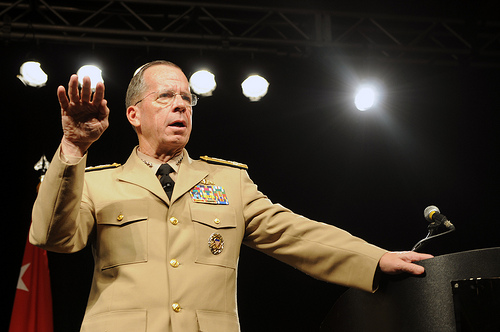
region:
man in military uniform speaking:
[20, 45, 470, 310]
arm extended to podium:
[245, 162, 430, 302]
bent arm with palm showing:
[22, 60, 112, 260]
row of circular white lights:
[5, 52, 295, 118]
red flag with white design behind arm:
[5, 145, 60, 320]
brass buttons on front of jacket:
[105, 196, 230, 316]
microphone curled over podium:
[401, 187, 456, 282]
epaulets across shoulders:
[81, 146, 253, 173]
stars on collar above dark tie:
[120, 150, 226, 206]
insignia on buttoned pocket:
[185, 208, 241, 263]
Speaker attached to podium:
[413, 198, 486, 250]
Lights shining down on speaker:
[198, 60, 401, 125]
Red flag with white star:
[14, 150, 57, 327]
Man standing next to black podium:
[32, 45, 454, 328]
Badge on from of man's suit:
[207, 229, 228, 256]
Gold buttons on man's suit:
[160, 207, 185, 317]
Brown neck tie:
[152, 162, 185, 202]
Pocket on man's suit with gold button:
[99, 195, 157, 275]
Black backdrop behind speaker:
[286, 120, 461, 199]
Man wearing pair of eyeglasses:
[126, 70, 205, 140]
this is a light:
[340, 79, 390, 117]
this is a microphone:
[421, 195, 449, 237]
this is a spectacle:
[154, 89, 198, 103]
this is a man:
[43, 67, 265, 327]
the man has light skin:
[143, 111, 160, 140]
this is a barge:
[196, 183, 222, 203]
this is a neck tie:
[160, 163, 170, 185]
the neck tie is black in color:
[163, 175, 165, 178]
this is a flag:
[21, 258, 53, 330]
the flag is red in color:
[31, 306, 41, 317]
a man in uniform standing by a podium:
[30, 62, 433, 329]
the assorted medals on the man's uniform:
[185, 178, 226, 203]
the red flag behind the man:
[12, 148, 67, 328]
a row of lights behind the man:
[9, 47, 405, 129]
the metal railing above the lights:
[1, 0, 498, 75]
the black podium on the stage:
[312, 243, 496, 330]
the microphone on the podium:
[405, 200, 455, 249]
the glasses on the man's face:
[132, 85, 197, 105]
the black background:
[302, 137, 491, 202]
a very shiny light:
[323, 66, 410, 157]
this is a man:
[12, 49, 286, 329]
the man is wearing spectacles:
[150, 92, 202, 104]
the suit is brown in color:
[82, 178, 247, 328]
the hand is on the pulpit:
[372, 232, 445, 287]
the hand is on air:
[30, 68, 124, 233]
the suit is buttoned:
[157, 208, 194, 323]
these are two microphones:
[417, 200, 467, 240]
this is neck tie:
[160, 160, 172, 185]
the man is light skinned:
[160, 70, 176, 79]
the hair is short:
[130, 69, 146, 94]